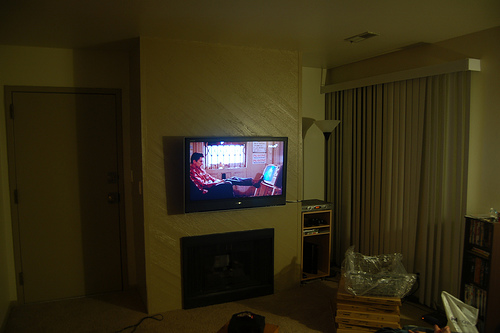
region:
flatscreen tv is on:
[180, 134, 289, 211]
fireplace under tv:
[179, 228, 274, 308]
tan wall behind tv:
[143, 39, 310, 313]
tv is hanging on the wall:
[180, 134, 290, 214]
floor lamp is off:
[312, 117, 342, 200]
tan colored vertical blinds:
[319, 58, 478, 312]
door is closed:
[10, 89, 130, 304]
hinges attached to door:
[11, 186, 19, 204]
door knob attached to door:
[106, 190, 117, 205]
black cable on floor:
[109, 311, 163, 331]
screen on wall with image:
[178, 137, 288, 204]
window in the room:
[326, 73, 465, 289]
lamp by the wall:
[304, 116, 347, 266]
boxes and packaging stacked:
[331, 240, 416, 332]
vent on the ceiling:
[330, 28, 384, 48]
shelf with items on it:
[467, 202, 497, 319]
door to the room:
[6, 85, 121, 296]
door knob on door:
[104, 190, 123, 205]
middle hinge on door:
[5, 188, 24, 210]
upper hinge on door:
[1, 100, 23, 121]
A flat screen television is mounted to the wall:
[172, 125, 300, 222]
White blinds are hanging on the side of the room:
[323, 63, 461, 329]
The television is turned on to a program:
[189, 140, 280, 202]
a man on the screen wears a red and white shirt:
[192, 151, 223, 193]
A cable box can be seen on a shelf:
[298, 197, 336, 214]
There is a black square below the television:
[176, 230, 284, 310]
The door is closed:
[5, 89, 143, 329]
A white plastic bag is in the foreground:
[438, 279, 486, 332]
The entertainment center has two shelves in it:
[301, 208, 337, 292]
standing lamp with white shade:
[314, 104, 349, 204]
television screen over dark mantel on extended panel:
[135, 16, 305, 308]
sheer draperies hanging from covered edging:
[325, 41, 476, 321]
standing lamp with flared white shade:
[310, 107, 340, 204]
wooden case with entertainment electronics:
[301, 192, 331, 277]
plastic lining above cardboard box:
[330, 245, 410, 325]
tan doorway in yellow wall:
[5, 50, 140, 320]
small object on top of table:
[136, 295, 301, 330]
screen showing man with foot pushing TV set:
[170, 125, 285, 205]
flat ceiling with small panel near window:
[11, 1, 486, 56]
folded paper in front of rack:
[437, 210, 497, 330]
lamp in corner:
[314, 115, 343, 196]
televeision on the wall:
[167, 138, 284, 213]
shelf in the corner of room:
[300, 214, 331, 284]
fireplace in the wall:
[183, 230, 273, 304]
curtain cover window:
[323, 88, 480, 280]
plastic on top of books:
[338, 248, 415, 295]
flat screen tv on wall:
[164, 138, 289, 206]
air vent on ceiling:
[345, 32, 375, 46]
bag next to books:
[433, 289, 483, 330]